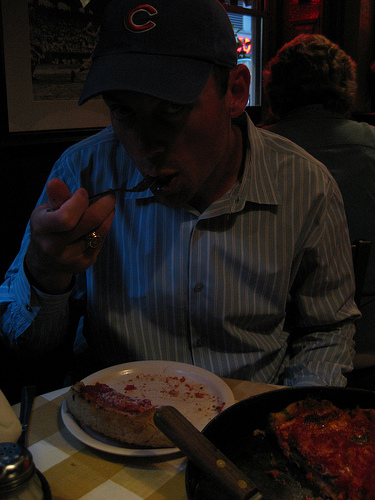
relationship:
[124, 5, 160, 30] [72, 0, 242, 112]
chicago symbol on cap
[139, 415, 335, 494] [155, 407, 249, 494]
knife has handle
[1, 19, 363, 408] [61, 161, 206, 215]
man holds fork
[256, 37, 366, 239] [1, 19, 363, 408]
woman behind man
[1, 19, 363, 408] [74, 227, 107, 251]
man has ring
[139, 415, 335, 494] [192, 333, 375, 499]
knife on platter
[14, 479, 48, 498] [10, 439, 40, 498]
cheese inside dispenser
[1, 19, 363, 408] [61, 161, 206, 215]
man eats with fork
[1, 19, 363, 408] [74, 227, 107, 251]
man wears ring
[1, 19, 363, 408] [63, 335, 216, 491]
man eats pizza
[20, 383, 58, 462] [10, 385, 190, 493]
silverware on table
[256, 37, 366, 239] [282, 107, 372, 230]
woman wears blouse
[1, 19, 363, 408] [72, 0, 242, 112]
man wears cap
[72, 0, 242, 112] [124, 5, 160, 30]
cap has chicago symbol